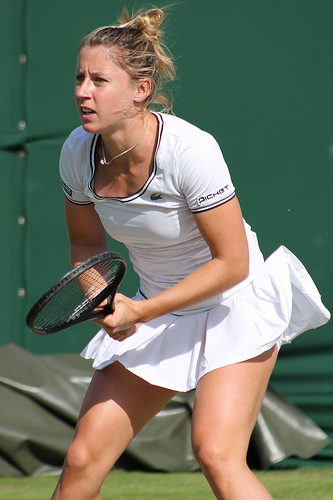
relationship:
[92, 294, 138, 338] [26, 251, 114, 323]
hands on racket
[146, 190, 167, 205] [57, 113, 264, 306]
logo on shirt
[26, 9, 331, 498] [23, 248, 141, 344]
woman holding tennis racket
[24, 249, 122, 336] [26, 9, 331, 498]
racket held by woman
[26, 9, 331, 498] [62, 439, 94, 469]
woman has knee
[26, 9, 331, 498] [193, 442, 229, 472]
woman has knee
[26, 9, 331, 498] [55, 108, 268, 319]
woman wearing shirt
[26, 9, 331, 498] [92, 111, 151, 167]
woman wearing necklace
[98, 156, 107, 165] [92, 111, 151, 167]
pendant on necklace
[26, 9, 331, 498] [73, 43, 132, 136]
woman has face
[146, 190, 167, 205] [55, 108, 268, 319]
logo on shirt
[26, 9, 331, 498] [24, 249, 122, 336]
woman holding racket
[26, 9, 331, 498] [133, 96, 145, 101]
woman wearing earring